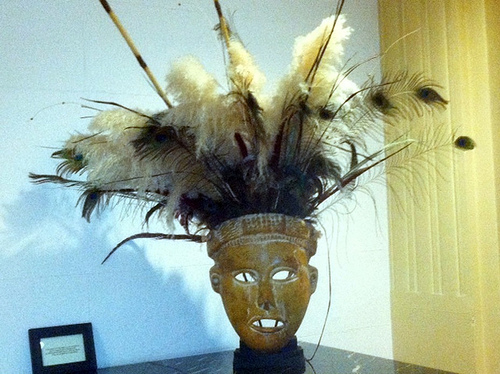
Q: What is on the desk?
A: A pot.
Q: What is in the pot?
A: Feathers.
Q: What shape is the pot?
A: Face.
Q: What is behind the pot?
A: Wall.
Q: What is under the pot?
A: A table.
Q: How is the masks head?
A: Feathery.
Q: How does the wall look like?
A: Blue.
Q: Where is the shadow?
A: On the wall.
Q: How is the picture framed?
A: In black.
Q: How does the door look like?
A: Yellow.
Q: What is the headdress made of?
A: Feathers.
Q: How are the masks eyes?
A: Opened.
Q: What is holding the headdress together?
A: A band.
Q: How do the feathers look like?
A: Black and white.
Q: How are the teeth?
A: WHITE.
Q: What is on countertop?
A: Black marble.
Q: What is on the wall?
A: Shadow.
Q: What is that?
A: A face.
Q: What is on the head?
A: Feathers.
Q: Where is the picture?
A: On the left side of the face.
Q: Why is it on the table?
A: For display.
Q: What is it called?
A: The mask.